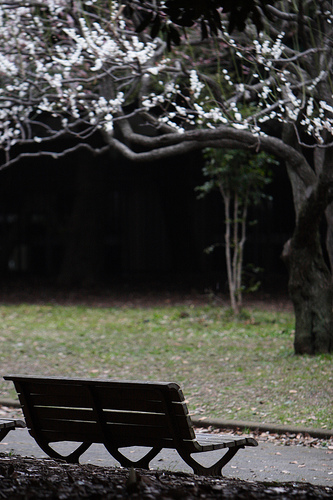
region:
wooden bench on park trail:
[5, 362, 247, 472]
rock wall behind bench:
[3, 448, 331, 498]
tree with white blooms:
[8, 3, 331, 357]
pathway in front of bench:
[2, 404, 331, 485]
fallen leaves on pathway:
[3, 400, 324, 481]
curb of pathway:
[5, 397, 328, 440]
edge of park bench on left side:
[0, 409, 26, 440]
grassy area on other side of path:
[19, 290, 328, 410]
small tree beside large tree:
[200, 75, 266, 323]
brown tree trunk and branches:
[112, 107, 327, 354]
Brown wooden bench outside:
[4, 367, 243, 476]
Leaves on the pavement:
[306, 431, 331, 446]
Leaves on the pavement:
[267, 430, 309, 449]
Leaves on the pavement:
[227, 424, 265, 440]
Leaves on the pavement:
[201, 423, 239, 436]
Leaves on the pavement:
[2, 402, 23, 421]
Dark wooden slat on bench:
[18, 404, 204, 425]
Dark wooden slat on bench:
[3, 368, 184, 397]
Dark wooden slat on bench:
[195, 426, 253, 452]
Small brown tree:
[212, 226, 254, 325]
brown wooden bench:
[5, 371, 258, 478]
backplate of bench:
[5, 373, 200, 456]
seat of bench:
[163, 428, 257, 450]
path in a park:
[1, 397, 330, 497]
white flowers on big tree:
[1, 0, 332, 148]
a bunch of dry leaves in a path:
[3, 397, 332, 482]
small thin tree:
[204, 139, 262, 315]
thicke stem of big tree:
[289, 200, 331, 351]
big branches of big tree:
[5, 1, 332, 178]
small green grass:
[3, 281, 331, 429]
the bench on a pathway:
[2, 371, 260, 481]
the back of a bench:
[5, 374, 202, 449]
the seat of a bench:
[200, 429, 263, 452]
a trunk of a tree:
[281, 199, 330, 358]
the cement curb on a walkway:
[253, 421, 317, 448]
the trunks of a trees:
[222, 218, 251, 321]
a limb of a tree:
[144, 126, 277, 146]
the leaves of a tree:
[214, 150, 255, 187]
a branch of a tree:
[29, 141, 103, 160]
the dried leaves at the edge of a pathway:
[262, 430, 317, 445]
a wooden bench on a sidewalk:
[16, 368, 247, 474]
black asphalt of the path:
[247, 446, 316, 481]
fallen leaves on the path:
[252, 425, 326, 458]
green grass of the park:
[111, 313, 230, 367]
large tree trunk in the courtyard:
[276, 167, 332, 361]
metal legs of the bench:
[33, 443, 253, 482]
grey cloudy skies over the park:
[21, 18, 115, 74]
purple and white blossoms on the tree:
[30, 27, 324, 144]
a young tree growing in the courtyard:
[204, 158, 259, 320]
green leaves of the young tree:
[194, 145, 267, 215]